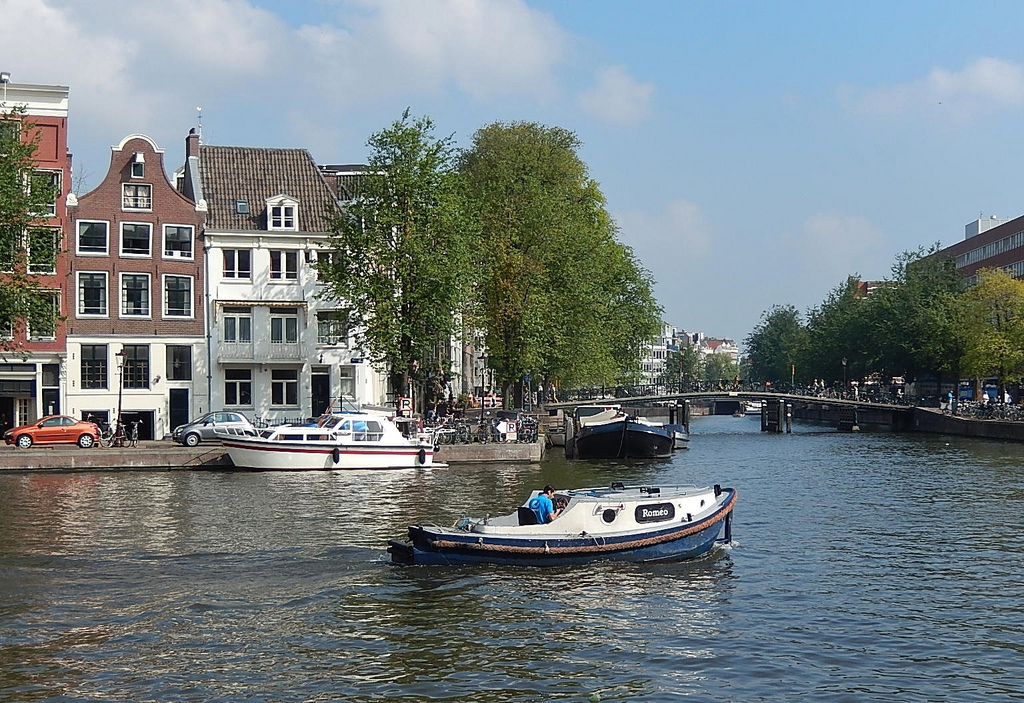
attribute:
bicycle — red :
[129, 418, 143, 447]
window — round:
[387, 479, 738, 566]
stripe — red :
[221, 440, 437, 456]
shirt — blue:
[527, 491, 554, 520]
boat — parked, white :
[220, 409, 436, 470]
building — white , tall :
[170, 104, 398, 428]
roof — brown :
[199, 147, 361, 234]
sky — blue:
[0, 0, 1022, 358]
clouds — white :
[0, 0, 1022, 356]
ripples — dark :
[2, 411, 1023, 700]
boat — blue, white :
[388, 484, 736, 564]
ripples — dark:
[838, 502, 945, 583]